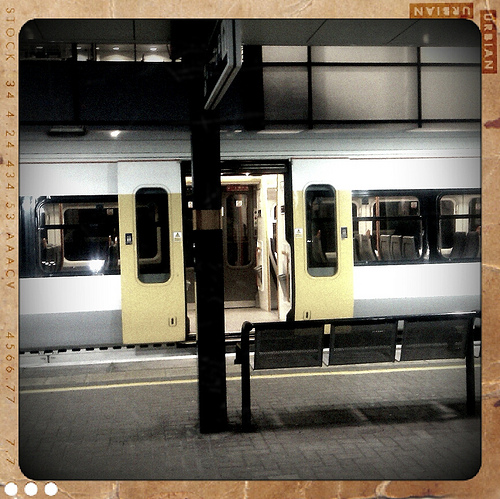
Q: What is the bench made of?
A: Metal.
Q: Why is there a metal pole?
A: It's holding up a sign.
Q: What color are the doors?
A: Pale yellow.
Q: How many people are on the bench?
A: None.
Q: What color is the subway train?
A: Silver.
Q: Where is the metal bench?
A: Near the entrance to trains.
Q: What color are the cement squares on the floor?
A: Grey.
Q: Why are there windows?
A: To look out.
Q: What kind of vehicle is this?
A: Train.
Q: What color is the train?
A: Silver.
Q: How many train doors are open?
A: One.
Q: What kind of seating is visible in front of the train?
A: Bench.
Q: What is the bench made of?
A: Metal.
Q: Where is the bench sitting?
A: Platform.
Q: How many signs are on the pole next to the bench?
A: One.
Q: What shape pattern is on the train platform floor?
A: Rectangles.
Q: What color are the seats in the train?
A: Tan.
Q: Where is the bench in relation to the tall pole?
A: Right.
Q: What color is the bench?
A: Black.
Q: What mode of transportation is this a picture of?
A: Train.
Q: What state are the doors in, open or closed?
A: Open.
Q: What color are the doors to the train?
A: Yellow.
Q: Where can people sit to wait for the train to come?
A: Bench.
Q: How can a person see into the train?
A: Windows.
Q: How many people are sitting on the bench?
A: Zero.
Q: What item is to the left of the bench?
A: Black column.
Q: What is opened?
A: Door of the train.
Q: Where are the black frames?
A: In the windows.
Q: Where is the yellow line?
A: On platform.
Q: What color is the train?
A: Silver.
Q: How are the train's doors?
A: Open.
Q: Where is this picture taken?
A: A train station.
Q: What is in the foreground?
A: A bench and pole.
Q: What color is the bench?
A: Black.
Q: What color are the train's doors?
A: Yellow.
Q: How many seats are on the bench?
A: Three.